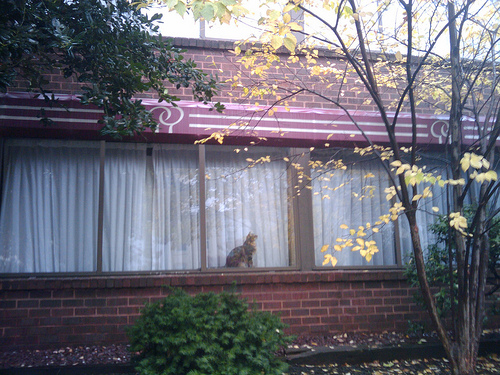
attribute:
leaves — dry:
[2, 335, 499, 371]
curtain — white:
[98, 141, 149, 273]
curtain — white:
[148, 142, 203, 274]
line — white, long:
[189, 120, 434, 142]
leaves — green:
[1, 0, 212, 140]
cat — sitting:
[218, 227, 270, 276]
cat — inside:
[216, 226, 260, 271]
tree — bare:
[190, 5, 495, 372]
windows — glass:
[35, 127, 495, 288]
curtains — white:
[6, 161, 445, 258]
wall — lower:
[9, 263, 494, 373]